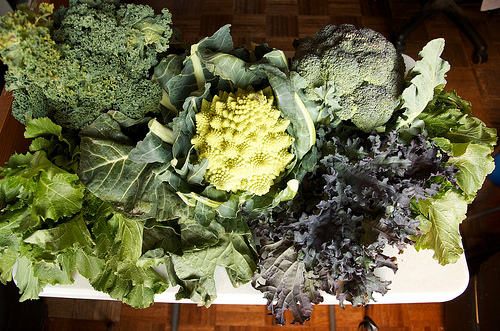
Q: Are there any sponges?
A: No, there are no sponges.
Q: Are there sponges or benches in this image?
A: No, there are no sponges or benches.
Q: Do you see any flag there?
A: No, there are no flags.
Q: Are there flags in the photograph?
A: No, there are no flags.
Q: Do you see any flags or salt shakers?
A: No, there are no flags or salt shakers.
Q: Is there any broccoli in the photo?
A: Yes, there is broccoli.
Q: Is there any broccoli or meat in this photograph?
A: Yes, there is broccoli.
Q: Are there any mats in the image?
A: No, there are no mats.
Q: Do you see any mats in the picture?
A: No, there are no mats.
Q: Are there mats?
A: No, there are no mats.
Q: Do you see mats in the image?
A: No, there are no mats.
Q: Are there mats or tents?
A: No, there are no mats or tents.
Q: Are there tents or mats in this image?
A: No, there are no mats or tents.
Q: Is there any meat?
A: No, there is no meat.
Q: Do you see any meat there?
A: No, there is no meat.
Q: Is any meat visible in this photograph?
A: No, there is no meat.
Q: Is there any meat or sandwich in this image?
A: No, there are no meat or sandwiches.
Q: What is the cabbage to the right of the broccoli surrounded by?
A: The cabbage is surrounded by the leaves.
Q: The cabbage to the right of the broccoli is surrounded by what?
A: The cabbage is surrounded by the leaves.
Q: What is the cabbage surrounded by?
A: The cabbage is surrounded by the leaves.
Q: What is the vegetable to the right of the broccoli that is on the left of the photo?
A: The vegetable is a cabbage.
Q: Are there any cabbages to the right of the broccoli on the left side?
A: Yes, there is a cabbage to the right of the broccoli.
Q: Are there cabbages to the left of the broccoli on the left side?
A: No, the cabbage is to the right of the broccoli.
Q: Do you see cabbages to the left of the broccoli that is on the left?
A: No, the cabbage is to the right of the broccoli.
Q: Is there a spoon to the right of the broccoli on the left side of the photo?
A: No, there is a cabbage to the right of the broccoli.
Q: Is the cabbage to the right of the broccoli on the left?
A: Yes, the cabbage is to the right of the broccoli.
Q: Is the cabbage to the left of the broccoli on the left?
A: No, the cabbage is to the right of the broccoli.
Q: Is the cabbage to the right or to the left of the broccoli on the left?
A: The cabbage is to the right of the broccoli.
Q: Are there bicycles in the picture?
A: No, there are no bicycles.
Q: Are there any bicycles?
A: No, there are no bicycles.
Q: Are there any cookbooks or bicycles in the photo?
A: No, there are no bicycles or cookbooks.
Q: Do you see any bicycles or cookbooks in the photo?
A: No, there are no bicycles or cookbooks.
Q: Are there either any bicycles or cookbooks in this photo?
A: No, there are no bicycles or cookbooks.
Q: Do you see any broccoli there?
A: Yes, there is broccoli.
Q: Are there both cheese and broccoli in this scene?
A: No, there is broccoli but no cheese.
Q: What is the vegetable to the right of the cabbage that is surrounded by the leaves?
A: The vegetable is broccoli.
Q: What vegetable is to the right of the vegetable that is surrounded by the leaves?
A: The vegetable is broccoli.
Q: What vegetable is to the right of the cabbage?
A: The vegetable is broccoli.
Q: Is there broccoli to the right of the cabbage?
A: Yes, there is broccoli to the right of the cabbage.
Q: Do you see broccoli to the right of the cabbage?
A: Yes, there is broccoli to the right of the cabbage.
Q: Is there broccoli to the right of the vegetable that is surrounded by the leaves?
A: Yes, there is broccoli to the right of the cabbage.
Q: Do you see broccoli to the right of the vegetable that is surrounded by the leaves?
A: Yes, there is broccoli to the right of the cabbage.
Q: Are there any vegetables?
A: Yes, there are vegetables.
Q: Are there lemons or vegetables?
A: Yes, there are vegetables.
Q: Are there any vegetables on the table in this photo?
A: Yes, there are vegetables on the table.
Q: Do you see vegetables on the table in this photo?
A: Yes, there are vegetables on the table.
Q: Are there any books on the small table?
A: No, there are vegetables on the table.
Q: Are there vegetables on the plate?
A: Yes, there are vegetables on the plate.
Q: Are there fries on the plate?
A: No, there are vegetables on the plate.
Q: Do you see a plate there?
A: Yes, there is a plate.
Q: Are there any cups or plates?
A: Yes, there is a plate.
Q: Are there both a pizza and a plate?
A: No, there is a plate but no pizzas.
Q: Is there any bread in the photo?
A: No, there is no breads.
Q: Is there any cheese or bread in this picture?
A: No, there are no breads or cheese.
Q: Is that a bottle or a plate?
A: That is a plate.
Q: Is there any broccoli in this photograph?
A: Yes, there is broccoli.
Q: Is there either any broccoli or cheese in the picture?
A: Yes, there is broccoli.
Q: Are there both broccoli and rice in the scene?
A: No, there is broccoli but no rice.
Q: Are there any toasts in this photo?
A: No, there are no toasts.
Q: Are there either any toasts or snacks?
A: No, there are no toasts or snacks.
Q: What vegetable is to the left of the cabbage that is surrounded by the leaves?
A: The vegetable is broccoli.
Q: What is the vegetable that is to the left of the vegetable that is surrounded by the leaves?
A: The vegetable is broccoli.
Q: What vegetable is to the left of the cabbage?
A: The vegetable is broccoli.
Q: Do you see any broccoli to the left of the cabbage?
A: Yes, there is broccoli to the left of the cabbage.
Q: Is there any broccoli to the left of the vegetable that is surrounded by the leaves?
A: Yes, there is broccoli to the left of the cabbage.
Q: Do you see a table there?
A: Yes, there is a table.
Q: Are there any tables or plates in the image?
A: Yes, there is a table.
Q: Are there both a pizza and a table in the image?
A: No, there is a table but no pizzas.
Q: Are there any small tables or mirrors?
A: Yes, there is a small table.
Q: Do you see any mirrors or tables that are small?
A: Yes, the table is small.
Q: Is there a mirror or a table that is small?
A: Yes, the table is small.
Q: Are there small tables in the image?
A: Yes, there is a small table.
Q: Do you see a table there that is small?
A: Yes, there is a table that is small.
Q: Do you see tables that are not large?
A: Yes, there is a small table.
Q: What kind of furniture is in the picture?
A: The furniture is a table.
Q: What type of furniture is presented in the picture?
A: The furniture is a table.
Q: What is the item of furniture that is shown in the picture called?
A: The piece of furniture is a table.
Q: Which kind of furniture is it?
A: The piece of furniture is a table.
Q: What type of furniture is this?
A: This is a table.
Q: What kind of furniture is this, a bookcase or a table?
A: This is a table.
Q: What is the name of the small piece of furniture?
A: The piece of furniture is a table.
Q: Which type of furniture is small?
A: The furniture is a table.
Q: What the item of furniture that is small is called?
A: The piece of furniture is a table.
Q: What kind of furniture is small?
A: The furniture is a table.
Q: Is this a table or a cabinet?
A: This is a table.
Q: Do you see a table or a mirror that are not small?
A: No, there is a table but it is small.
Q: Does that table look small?
A: Yes, the table is small.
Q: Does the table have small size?
A: Yes, the table is small.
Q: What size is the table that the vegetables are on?
A: The table is small.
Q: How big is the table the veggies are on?
A: The table is small.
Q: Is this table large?
A: No, the table is small.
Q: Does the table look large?
A: No, the table is small.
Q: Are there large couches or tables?
A: No, there is a table but it is small.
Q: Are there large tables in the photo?
A: No, there is a table but it is small.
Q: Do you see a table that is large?
A: No, there is a table but it is small.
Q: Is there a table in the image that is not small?
A: No, there is a table but it is small.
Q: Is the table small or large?
A: The table is small.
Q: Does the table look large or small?
A: The table is small.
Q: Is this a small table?
A: Yes, this is a small table.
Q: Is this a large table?
A: No, this is a small table.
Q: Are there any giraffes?
A: No, there are no giraffes.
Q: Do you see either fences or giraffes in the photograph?
A: No, there are no giraffes or fences.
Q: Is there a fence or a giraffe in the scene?
A: No, there are no giraffes or fences.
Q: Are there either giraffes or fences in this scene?
A: No, there are no giraffes or fences.